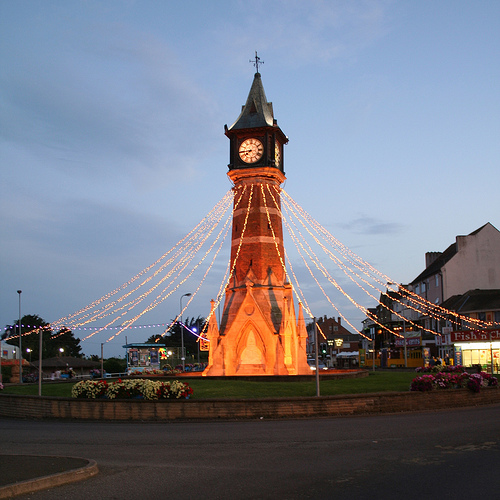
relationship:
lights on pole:
[3, 184, 498, 376] [201, 56, 314, 366]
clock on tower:
[198, 110, 302, 195] [162, 63, 369, 371]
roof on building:
[417, 245, 458, 273] [423, 222, 498, 303]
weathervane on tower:
[246, 48, 268, 73] [206, 52, 316, 373]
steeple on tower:
[227, 51, 279, 131] [206, 52, 316, 373]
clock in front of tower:
[233, 129, 268, 166] [154, 33, 310, 415]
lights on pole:
[3, 184, 498, 376] [133, 301, 208, 368]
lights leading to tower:
[14, 184, 479, 373] [170, 60, 309, 334]